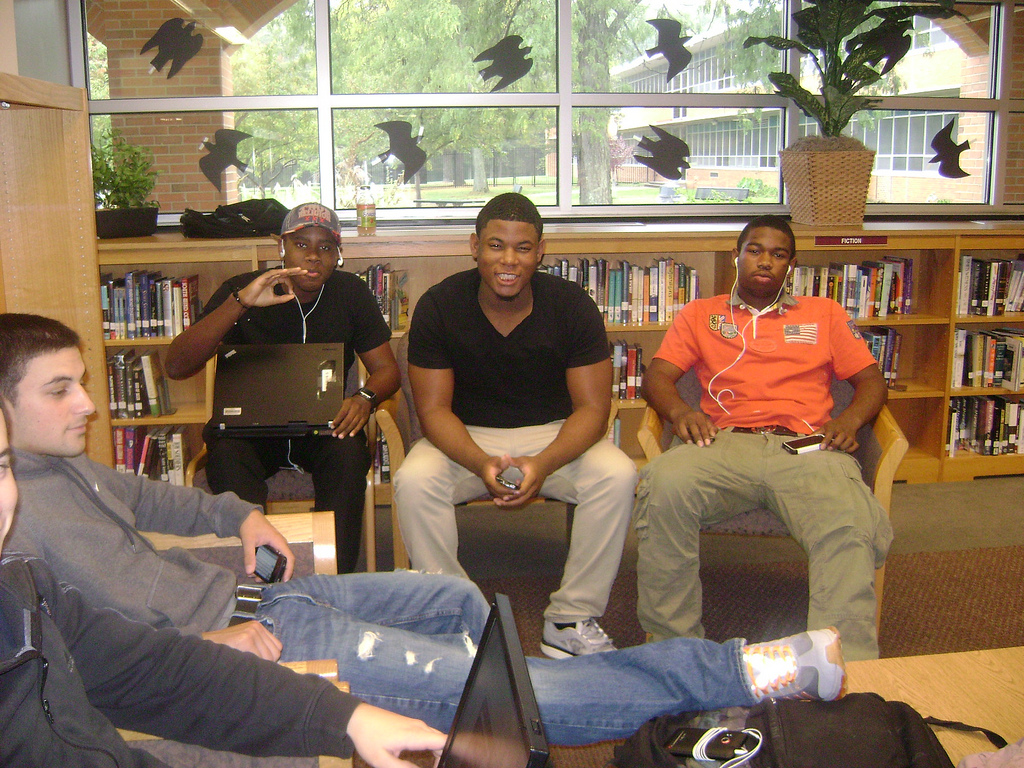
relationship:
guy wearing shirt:
[231, 163, 402, 341] [404, 297, 586, 434]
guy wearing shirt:
[421, 180, 603, 401] [188, 262, 409, 446]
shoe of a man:
[698, 577, 912, 716] [10, 301, 177, 647]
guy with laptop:
[183, 200, 402, 499] [206, 344, 348, 437]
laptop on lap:
[206, 344, 348, 437] [190, 408, 374, 560]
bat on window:
[140, 14, 205, 77] [84, 3, 316, 101]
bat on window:
[473, 33, 530, 90] [326, 1, 556, 94]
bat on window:
[641, 16, 694, 81] [570, 3, 787, 88]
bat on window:
[630, 121, 693, 180] [572, 107, 784, 203]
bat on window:
[928, 121, 972, 182] [803, 107, 994, 203]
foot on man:
[537, 608, 618, 665] [395, 191, 631, 656]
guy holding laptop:
[183, 200, 402, 499] [207, 344, 348, 437]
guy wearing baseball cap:
[183, 200, 402, 499] [276, 202, 344, 250]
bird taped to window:
[371, 117, 426, 184] [334, 107, 557, 203]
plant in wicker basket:
[743, 3, 968, 137] [779, 148, 877, 235]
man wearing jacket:
[2, 314, 845, 747] [6, 446, 259, 634]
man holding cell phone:
[2, 314, 845, 747] [254, 543, 289, 583]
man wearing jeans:
[2, 314, 845, 747] [250, 567, 762, 745]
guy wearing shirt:
[628, 212, 893, 650] [658, 290, 877, 431]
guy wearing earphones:
[628, 212, 893, 650] [706, 251, 825, 442]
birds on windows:
[138, 5, 975, 193] [82, 3, 1022, 217]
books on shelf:
[99, 256, 1022, 485] [94, 217, 1021, 513]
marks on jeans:
[354, 625, 482, 675] [250, 567, 762, 745]